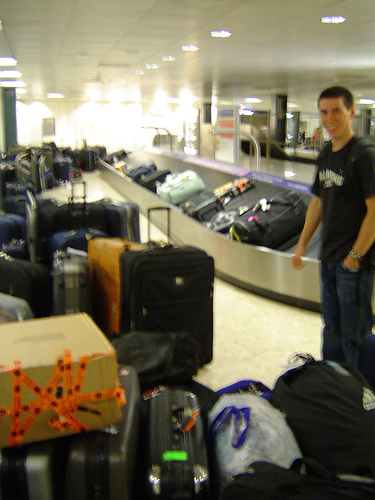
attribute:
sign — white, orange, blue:
[200, 105, 243, 162]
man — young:
[290, 86, 373, 390]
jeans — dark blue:
[314, 253, 374, 388]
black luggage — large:
[117, 204, 225, 361]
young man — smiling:
[289, 81, 368, 371]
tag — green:
[160, 446, 193, 462]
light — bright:
[0, 55, 18, 66]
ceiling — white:
[0, 0, 374, 111]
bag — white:
[212, 380, 266, 446]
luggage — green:
[157, 167, 207, 203]